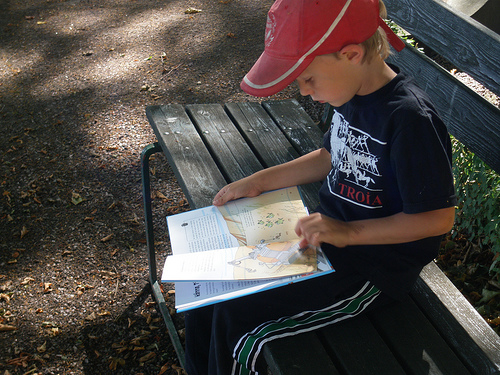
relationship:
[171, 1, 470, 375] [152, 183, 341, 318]
boy holding book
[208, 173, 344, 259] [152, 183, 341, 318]
hands on book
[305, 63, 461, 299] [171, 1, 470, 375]
shirt on boy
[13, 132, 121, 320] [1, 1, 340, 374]
leaves on ground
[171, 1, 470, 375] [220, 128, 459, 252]
boy has arms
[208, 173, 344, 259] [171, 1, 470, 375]
hands on boy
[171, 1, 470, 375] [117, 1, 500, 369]
boy on bench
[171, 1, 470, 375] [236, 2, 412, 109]
boy wearing hat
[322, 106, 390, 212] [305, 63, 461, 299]
logo on shirt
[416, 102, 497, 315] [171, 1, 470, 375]
bush behind boy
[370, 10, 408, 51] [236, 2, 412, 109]
strap on hat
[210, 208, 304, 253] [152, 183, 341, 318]
design in book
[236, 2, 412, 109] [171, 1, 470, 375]
hat on top of boy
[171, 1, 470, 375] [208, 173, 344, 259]
boy has hands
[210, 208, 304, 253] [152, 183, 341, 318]
design inside book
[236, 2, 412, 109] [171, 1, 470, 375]
hat on boy